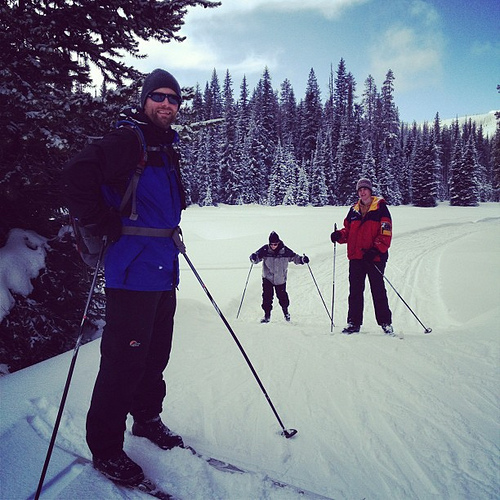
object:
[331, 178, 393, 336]
people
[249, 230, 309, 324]
people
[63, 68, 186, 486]
people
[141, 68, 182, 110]
hat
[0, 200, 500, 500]
snow